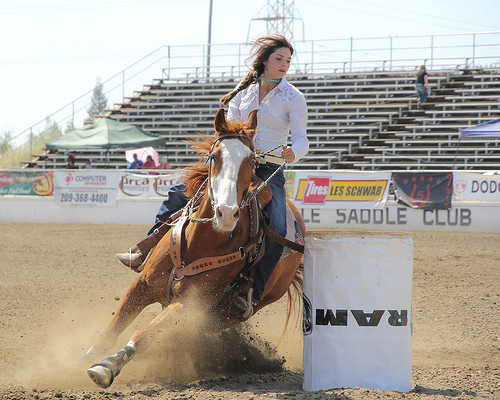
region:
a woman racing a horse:
[77, 3, 430, 392]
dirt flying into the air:
[176, 324, 233, 360]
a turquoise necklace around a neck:
[245, 71, 277, 85]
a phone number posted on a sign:
[54, 187, 114, 209]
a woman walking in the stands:
[410, 45, 451, 117]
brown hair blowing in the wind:
[251, 39, 265, 60]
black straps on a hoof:
[91, 353, 139, 371]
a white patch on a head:
[219, 136, 254, 224]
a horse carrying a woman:
[116, 106, 300, 375]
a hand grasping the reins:
[269, 131, 295, 171]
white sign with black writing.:
[267, 208, 450, 398]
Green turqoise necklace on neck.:
[243, 73, 283, 90]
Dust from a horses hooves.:
[68, 253, 300, 398]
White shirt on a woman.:
[206, 72, 317, 175]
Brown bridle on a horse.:
[132, 226, 277, 298]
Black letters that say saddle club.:
[318, 203, 479, 238]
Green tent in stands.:
[14, 103, 157, 193]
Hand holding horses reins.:
[244, 122, 320, 226]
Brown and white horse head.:
[178, 134, 288, 243]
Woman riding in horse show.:
[61, 4, 336, 398]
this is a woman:
[230, 46, 317, 112]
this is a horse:
[185, 164, 306, 292]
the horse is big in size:
[118, 156, 273, 376]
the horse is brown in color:
[168, 189, 260, 313]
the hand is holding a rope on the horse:
[272, 135, 295, 180]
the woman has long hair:
[218, 67, 256, 99]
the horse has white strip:
[221, 145, 247, 209]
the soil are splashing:
[195, 334, 267, 391]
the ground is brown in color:
[1, 239, 87, 349]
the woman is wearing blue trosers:
[273, 179, 281, 208]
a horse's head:
[199, 101, 269, 248]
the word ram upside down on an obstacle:
[311, 283, 410, 341]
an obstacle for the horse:
[300, 213, 419, 390]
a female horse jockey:
[127, 19, 312, 329]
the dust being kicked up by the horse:
[27, 253, 280, 398]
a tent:
[43, 110, 178, 179]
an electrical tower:
[248, 0, 320, 73]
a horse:
[55, 97, 308, 399]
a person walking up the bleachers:
[397, 49, 435, 101]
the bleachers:
[1, 30, 499, 182]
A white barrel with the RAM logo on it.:
[294, 218, 418, 394]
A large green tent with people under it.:
[51, 111, 165, 156]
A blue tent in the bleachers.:
[448, 112, 498, 159]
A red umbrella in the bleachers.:
[122, 141, 159, 173]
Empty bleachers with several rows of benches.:
[1, 26, 498, 229]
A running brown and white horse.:
[68, 114, 325, 386]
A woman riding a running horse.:
[116, 21, 333, 289]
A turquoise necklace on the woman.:
[244, 66, 290, 90]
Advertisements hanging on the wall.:
[3, 159, 488, 230]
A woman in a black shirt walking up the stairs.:
[403, 50, 433, 110]